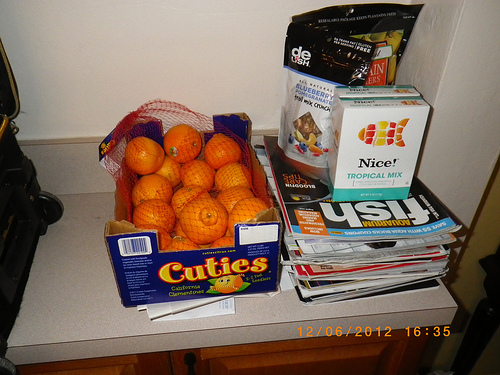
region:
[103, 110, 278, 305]
a box of bagged oranges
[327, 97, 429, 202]
a box of food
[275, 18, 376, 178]
a bag of food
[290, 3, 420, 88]
a bag of food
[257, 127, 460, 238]
a fish magazine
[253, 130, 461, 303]
a stack of magazines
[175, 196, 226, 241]
a round orange fruit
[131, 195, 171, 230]
a round orange fruit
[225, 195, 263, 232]
a round orange fruit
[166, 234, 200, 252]
a round orange fruit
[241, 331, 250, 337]
edge of a top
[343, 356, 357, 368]
part of a board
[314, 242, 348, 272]
part of a magazine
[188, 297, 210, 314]
part of a paper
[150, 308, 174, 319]
edge of a paper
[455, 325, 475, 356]
part of a stand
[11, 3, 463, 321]
kitchen counter area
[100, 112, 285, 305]
oranges in box on kitchen counter area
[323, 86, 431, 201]
boxes of tropical trail mixes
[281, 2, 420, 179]
bags of different trail mixes behind boxes of trail mixes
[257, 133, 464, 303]
magazines under boxes and bag of trail mixes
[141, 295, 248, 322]
papers under boxes of fruit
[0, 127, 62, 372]
suitcase on top of kitchen counter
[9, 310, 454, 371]
kitchen counter top and cabinets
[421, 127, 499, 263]
side wall of kitchen counter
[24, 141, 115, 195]
back of kitchen counter top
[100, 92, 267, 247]
Orange net bag over oranges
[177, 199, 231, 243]
Orange next to orange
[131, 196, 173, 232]
Orange next to orange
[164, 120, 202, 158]
Orange next to orange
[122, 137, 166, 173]
Orange next to orange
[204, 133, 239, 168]
Orange next to orange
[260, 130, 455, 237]
Magazine next to cardboard box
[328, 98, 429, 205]
Box on top of magazine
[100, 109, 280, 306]
Cardboard box on counter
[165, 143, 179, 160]
Sticker on orange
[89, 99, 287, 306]
full clementines blue box with red bag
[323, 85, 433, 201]
box of tropic fish food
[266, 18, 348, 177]
bag of blueberry fish food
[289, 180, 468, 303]
stack of fish magazines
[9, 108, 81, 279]
side of black suitcase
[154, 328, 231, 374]
black handle of cabinet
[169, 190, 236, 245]
clementine orange fruit in bag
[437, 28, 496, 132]
white corner wall drywall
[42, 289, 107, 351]
top of cabinet grey color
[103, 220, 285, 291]
cuties blue box